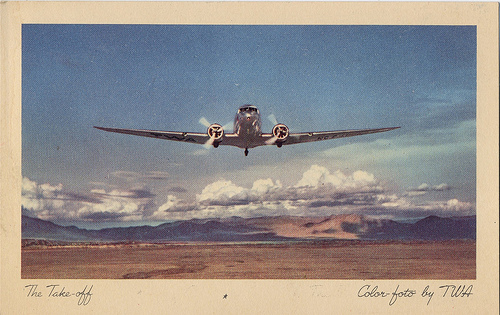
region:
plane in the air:
[103, 60, 398, 208]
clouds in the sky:
[98, 170, 266, 233]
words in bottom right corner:
[323, 255, 488, 313]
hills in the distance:
[156, 201, 334, 250]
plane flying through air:
[91, 97, 403, 167]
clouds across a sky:
[21, 165, 406, 226]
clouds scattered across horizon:
[25, 160, 466, 227]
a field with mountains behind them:
[24, 205, 468, 275]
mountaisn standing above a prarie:
[24, 210, 472, 272]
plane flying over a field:
[91, 94, 402, 266]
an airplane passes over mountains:
[85, 101, 403, 241]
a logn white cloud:
[201, 165, 385, 210]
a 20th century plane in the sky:
[92, 97, 404, 172]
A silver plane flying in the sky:
[91, 97, 408, 159]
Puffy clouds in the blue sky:
[34, 170, 379, 206]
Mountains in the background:
[43, 213, 469, 240]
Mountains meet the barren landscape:
[33, 208, 420, 277]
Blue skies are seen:
[91, 39, 422, 106]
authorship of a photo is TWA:
[349, 281, 490, 306]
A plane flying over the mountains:
[78, 82, 410, 247]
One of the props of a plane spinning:
[268, 115, 298, 146]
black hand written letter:
[23, 280, 36, 299]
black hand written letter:
[35, 289, 45, 299]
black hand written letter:
[46, 280, 58, 299]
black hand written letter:
[49, 288, 60, 299]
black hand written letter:
[58, 283, 68, 300]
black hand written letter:
[64, 289, 73, 296]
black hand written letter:
[73, 287, 82, 298]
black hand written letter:
[76, 284, 86, 304]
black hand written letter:
[82, 284, 94, 310]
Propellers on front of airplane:
[196, 108, 301, 152]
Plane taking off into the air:
[92, 101, 404, 157]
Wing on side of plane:
[295, 125, 405, 142]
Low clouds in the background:
[23, 161, 474, 221]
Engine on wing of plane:
[271, 123, 287, 140]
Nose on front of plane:
[244, 114, 251, 121]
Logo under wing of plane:
[144, 130, 196, 144]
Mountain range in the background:
[21, 211, 478, 246]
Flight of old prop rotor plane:
[93, 103, 403, 158]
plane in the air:
[107, 52, 429, 189]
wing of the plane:
[293, 106, 405, 168]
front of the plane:
[216, 90, 271, 147]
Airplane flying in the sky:
[28, 93, 369, 208]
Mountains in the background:
[81, 175, 428, 257]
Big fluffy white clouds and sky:
[112, 141, 429, 248]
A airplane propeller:
[261, 113, 325, 160]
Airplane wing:
[89, 125, 235, 148]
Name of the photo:
[15, 268, 112, 313]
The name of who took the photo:
[338, 261, 497, 311]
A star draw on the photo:
[194, 275, 239, 314]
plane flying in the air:
[88, 103, 402, 158]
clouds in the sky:
[18, 25, 478, 221]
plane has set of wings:
[94, 104, 401, 156]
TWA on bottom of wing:
[92, 122, 235, 149]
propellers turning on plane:
[94, 103, 400, 158]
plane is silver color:
[91, 103, 400, 157]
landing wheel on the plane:
[90, 105, 400, 158]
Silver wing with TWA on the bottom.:
[91, 124, 237, 147]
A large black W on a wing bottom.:
[163, 134, 185, 141]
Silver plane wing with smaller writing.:
[258, 125, 400, 145]